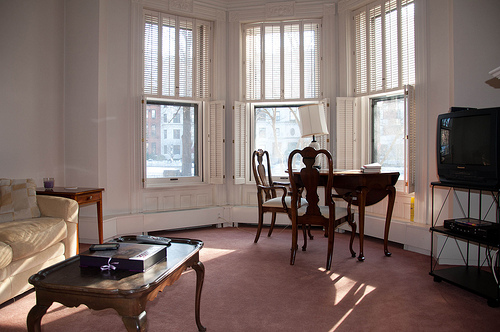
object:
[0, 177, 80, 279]
couch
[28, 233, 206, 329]
table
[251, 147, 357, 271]
chairs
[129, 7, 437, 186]
window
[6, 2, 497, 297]
room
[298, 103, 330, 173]
lamp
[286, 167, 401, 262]
table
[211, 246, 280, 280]
carpet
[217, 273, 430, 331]
floor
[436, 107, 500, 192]
tv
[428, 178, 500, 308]
stand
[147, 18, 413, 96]
shutters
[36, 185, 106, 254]
table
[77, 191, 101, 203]
drawer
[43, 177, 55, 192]
candle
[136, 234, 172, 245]
remote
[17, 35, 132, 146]
walls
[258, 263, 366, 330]
shadows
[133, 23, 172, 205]
edges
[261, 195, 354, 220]
seats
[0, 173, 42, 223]
pillows